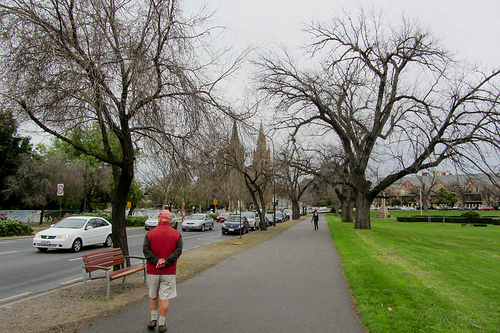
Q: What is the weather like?
A: Cloudy.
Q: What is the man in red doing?
A: Standing up.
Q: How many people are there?
A: Two.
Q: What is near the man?
A: A bench.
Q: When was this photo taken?
A: During the day.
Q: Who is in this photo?
A: Two people.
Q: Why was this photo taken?
A: To show the view.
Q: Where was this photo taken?
A: Outside on the sidewalk.